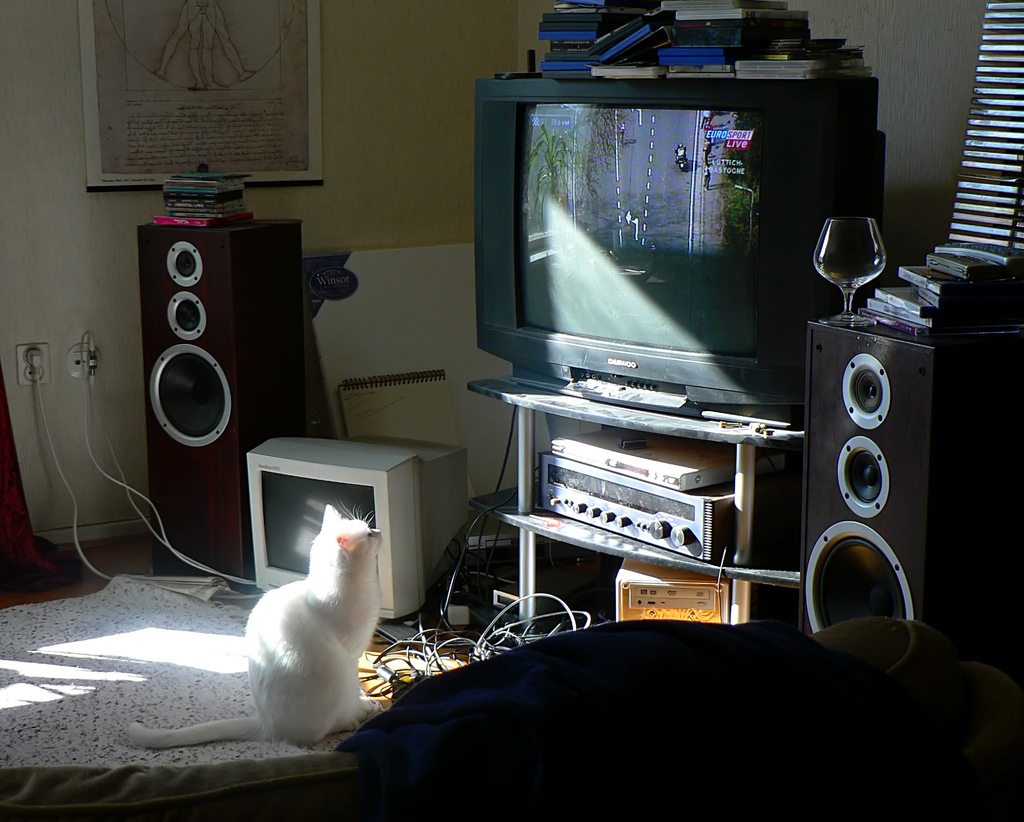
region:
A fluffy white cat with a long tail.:
[125, 502, 385, 746]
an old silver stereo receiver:
[535, 449, 741, 563]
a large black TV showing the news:
[469, 76, 890, 435]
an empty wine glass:
[811, 208, 885, 330]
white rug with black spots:
[1, 569, 390, 778]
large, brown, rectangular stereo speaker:
[134, 221, 313, 585]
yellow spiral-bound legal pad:
[334, 366, 477, 528]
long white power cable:
[14, 339, 112, 589]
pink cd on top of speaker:
[148, 212, 262, 229]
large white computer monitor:
[245, 423, 474, 621]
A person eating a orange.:
[502, 489, 570, 620]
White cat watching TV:
[138, 504, 395, 743]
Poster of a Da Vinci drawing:
[103, 0, 313, 174]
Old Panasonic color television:
[470, 79, 886, 403]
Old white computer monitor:
[251, 433, 487, 620]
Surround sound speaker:
[142, 220, 289, 578]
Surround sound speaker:
[809, 309, 1019, 641]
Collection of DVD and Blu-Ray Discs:
[542, 5, 871, 85]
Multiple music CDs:
[944, 3, 1021, 256]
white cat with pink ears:
[122, 499, 386, 750]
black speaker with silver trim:
[138, 217, 303, 571]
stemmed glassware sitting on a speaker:
[809, 212, 889, 327]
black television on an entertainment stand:
[464, 70, 883, 418]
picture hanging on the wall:
[72, 2, 329, 198]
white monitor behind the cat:
[245, 433, 473, 624]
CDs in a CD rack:
[947, 0, 1023, 257]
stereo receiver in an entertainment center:
[534, 449, 737, 560]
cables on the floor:
[359, 590, 597, 707]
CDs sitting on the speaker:
[152, 164, 252, 234]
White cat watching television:
[112, 504, 389, 751]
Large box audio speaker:
[134, 219, 300, 575]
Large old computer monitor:
[246, 434, 465, 618]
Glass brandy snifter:
[809, 216, 885, 330]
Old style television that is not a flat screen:
[471, 74, 889, 426]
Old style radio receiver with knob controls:
[538, 450, 734, 559]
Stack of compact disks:
[870, 1, 1019, 331]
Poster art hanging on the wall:
[77, 0, 327, 188]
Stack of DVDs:
[538, 0, 872, 80]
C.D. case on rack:
[945, 230, 1021, 251]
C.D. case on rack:
[961, 129, 1020, 152]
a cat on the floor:
[263, 529, 441, 751]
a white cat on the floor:
[285, 489, 396, 712]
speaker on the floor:
[818, 261, 983, 571]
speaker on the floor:
[158, 210, 285, 406]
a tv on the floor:
[480, 49, 759, 443]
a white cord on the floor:
[26, 327, 132, 441]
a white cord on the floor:
[467, 565, 646, 668]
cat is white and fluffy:
[120, 493, 384, 737]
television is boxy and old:
[477, 73, 816, 406]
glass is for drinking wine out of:
[809, 214, 883, 325]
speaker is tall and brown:
[138, 218, 303, 580]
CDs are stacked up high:
[944, 0, 1021, 249]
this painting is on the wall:
[79, 3, 323, 184]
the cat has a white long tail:
[119, 699, 269, 753]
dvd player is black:
[539, 443, 718, 558]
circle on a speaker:
[128, 345, 236, 451]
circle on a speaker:
[159, 285, 223, 343]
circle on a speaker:
[157, 232, 216, 284]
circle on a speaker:
[792, 519, 936, 646]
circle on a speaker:
[839, 431, 897, 515]